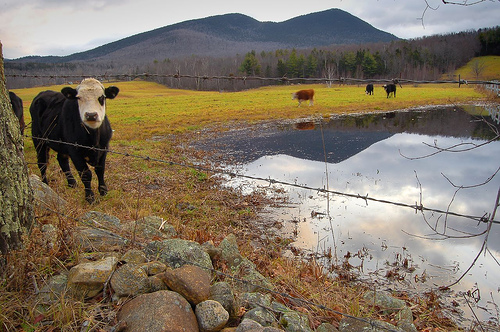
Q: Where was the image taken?
A: It was taken at the pasture.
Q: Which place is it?
A: It is a pasture.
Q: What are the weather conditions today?
A: It is cloudy.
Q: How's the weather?
A: It is cloudy.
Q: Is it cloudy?
A: Yes, it is cloudy.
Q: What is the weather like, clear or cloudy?
A: It is cloudy.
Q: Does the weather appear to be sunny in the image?
A: No, it is cloudy.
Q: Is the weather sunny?
A: No, it is cloudy.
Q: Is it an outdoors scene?
A: Yes, it is outdoors.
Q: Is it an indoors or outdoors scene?
A: It is outdoors.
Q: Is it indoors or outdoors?
A: It is outdoors.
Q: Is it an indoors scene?
A: No, it is outdoors.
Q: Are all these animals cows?
A: Yes, all the animals are cows.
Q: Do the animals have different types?
A: No, all the animals are cows.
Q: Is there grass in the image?
A: Yes, there is grass.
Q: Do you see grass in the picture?
A: Yes, there is grass.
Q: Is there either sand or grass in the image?
A: Yes, there is grass.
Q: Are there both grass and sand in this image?
A: No, there is grass but no sand.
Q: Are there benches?
A: No, there are no benches.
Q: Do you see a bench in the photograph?
A: No, there are no benches.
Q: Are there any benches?
A: No, there are no benches.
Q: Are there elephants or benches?
A: No, there are no benches or elephants.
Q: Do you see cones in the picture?
A: No, there are no cones.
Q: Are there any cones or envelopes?
A: No, there are no cones or envelopes.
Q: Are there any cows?
A: Yes, there is a cow.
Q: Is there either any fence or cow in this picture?
A: Yes, there is a cow.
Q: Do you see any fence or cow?
A: Yes, there is a cow.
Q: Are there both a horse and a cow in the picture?
A: No, there is a cow but no horses.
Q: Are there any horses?
A: No, there are no horses.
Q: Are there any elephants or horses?
A: No, there are no horses or elephants.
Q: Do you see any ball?
A: No, there are no balls.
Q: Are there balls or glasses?
A: No, there are no balls or glasses.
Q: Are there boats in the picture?
A: No, there are no boats.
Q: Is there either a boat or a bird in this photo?
A: No, there are no boats or birds.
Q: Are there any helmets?
A: No, there are no helmets.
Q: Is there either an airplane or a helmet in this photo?
A: No, there are no helmets or airplanes.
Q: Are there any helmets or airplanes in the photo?
A: No, there are no helmets or airplanes.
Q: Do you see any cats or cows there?
A: Yes, there is a cow.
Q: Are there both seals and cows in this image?
A: No, there is a cow but no seals.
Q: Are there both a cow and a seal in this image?
A: No, there is a cow but no seals.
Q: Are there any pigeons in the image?
A: No, there are no pigeons.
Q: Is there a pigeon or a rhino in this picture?
A: No, there are no pigeons or rhinos.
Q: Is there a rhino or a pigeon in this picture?
A: No, there are no pigeons or rhinos.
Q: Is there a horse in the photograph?
A: No, there are no horses.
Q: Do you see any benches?
A: No, there are no benches.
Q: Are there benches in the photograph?
A: No, there are no benches.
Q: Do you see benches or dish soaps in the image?
A: No, there are no benches or dish soaps.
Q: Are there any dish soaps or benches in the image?
A: No, there are no benches or dish soaps.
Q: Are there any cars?
A: No, there are no cars.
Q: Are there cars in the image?
A: No, there are no cars.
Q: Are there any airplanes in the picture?
A: No, there are no airplanes.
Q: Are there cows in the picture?
A: Yes, there is a cow.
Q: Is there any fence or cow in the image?
A: Yes, there is a cow.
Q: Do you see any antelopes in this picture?
A: No, there are no antelopes.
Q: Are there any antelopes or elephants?
A: No, there are no antelopes or elephants.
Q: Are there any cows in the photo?
A: Yes, there is a cow.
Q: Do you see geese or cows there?
A: Yes, there is a cow.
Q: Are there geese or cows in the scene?
A: Yes, there is a cow.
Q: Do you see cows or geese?
A: Yes, there is a cow.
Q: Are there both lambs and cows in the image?
A: No, there is a cow but no lambs.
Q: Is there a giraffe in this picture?
A: No, there are no giraffes.